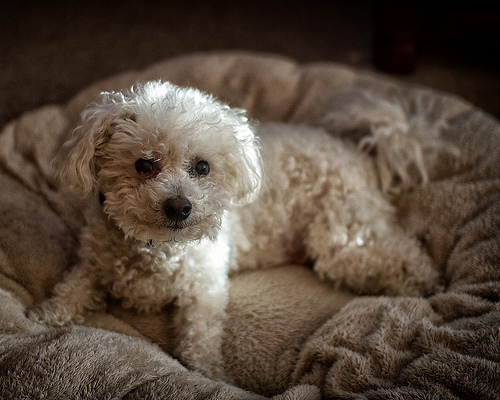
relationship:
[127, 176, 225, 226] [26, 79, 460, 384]
mouth of dog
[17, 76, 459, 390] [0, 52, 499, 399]
dog laying inside bed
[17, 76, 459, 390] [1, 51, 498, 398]
dog sitting on pillow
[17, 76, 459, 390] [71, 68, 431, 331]
dog with hair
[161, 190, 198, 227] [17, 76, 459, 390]
nose on dog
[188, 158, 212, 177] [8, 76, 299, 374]
eye on dog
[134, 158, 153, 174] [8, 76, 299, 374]
dark eyes on dog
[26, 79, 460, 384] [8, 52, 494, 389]
dog in bed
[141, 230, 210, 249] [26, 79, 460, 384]
small beard on dog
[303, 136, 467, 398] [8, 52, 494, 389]
folds in bed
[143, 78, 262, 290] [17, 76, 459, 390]
light on dog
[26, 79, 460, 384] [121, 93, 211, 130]
dog has fur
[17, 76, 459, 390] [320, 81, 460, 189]
dog has tail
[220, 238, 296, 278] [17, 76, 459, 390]
belly under dog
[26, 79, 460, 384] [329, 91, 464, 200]
dog has tail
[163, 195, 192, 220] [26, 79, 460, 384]
nose on dog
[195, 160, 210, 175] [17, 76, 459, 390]
eye on dog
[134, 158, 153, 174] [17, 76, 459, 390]
dark eyes on dog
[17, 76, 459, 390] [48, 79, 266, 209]
dog has curly hair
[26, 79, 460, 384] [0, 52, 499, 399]
dog laying in bed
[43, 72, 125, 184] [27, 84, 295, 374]
ear on dog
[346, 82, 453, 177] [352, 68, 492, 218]
tail flopping direction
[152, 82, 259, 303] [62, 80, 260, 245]
light falling over head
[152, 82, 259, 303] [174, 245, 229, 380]
light falling over leg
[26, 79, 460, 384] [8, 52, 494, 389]
dog laying bed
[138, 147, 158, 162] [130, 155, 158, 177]
fur covering eye